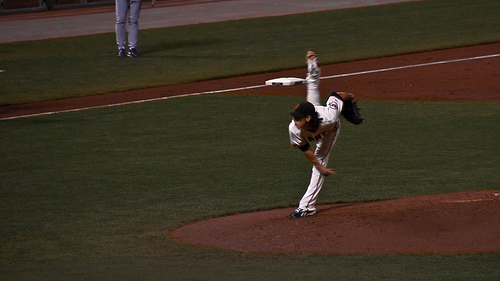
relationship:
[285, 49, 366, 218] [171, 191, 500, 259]
baseball player on mound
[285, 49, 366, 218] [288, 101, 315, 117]
baseball player wearing a hat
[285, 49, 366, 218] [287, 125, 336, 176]
baseball player has an arm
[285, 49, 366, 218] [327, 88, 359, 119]
baseball player has an arm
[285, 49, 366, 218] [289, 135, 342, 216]
baseball player has a leg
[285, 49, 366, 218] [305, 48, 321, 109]
baseball player has a leg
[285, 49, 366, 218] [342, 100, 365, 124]
baseball player wearing a glove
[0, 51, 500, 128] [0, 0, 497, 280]
line on field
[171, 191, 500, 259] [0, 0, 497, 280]
mound on field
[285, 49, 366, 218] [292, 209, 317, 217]
baseball player wearing a shoe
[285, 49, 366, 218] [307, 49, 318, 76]
baseball player wearing a shoe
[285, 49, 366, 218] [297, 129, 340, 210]
baseball player wearing trousers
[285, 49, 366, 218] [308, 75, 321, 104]
baseball player wearing trousers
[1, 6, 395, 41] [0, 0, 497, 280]
edge of field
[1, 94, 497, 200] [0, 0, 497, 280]
grass on field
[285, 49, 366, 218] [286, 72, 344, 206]
baseball player wearing a uniform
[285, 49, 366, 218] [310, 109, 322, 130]
baseball player has hair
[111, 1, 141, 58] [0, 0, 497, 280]
person on side of field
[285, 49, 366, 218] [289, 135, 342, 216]
baseball player balances on leg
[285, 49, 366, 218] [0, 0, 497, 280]
baseball player on field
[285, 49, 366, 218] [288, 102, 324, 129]
baseball player has a head